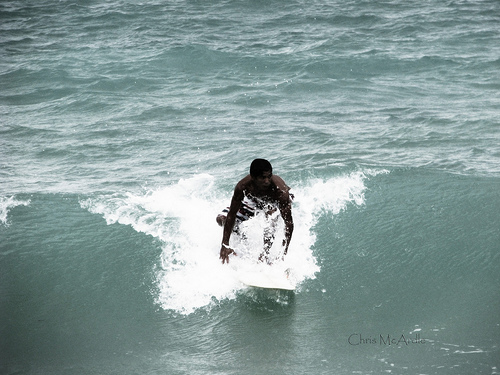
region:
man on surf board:
[179, 141, 305, 281]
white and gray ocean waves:
[350, 259, 375, 284]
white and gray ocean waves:
[282, 58, 306, 79]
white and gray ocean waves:
[42, 282, 80, 302]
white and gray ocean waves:
[193, 313, 228, 340]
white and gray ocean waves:
[286, 306, 331, 340]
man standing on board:
[207, 149, 302, 281]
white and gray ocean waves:
[367, 238, 401, 268]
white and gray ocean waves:
[347, 265, 384, 295]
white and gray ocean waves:
[46, 283, 123, 325]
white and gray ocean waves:
[93, 193, 137, 237]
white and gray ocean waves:
[385, 88, 435, 152]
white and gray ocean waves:
[280, 69, 325, 113]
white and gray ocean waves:
[182, 49, 219, 99]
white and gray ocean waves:
[136, 202, 168, 244]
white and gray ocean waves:
[129, 296, 204, 333]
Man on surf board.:
[212, 158, 303, 293]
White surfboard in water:
[237, 260, 301, 293]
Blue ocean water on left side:
[23, 228, 125, 330]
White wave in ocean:
[122, 186, 217, 306]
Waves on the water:
[48, 43, 210, 134]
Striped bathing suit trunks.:
[217, 196, 260, 231]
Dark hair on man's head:
[248, 155, 275, 193]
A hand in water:
[208, 241, 238, 268]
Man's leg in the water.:
[232, 214, 253, 246]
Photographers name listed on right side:
[341, 330, 427, 349]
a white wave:
[171, 252, 217, 299]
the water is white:
[164, 284, 206, 311]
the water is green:
[408, 173, 465, 221]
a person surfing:
[223, 163, 304, 265]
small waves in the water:
[17, 67, 114, 106]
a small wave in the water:
[314, 58, 410, 85]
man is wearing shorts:
[241, 203, 258, 221]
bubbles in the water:
[397, 315, 478, 367]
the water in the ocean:
[371, 245, 465, 320]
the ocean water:
[352, 290, 412, 330]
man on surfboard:
[197, 151, 309, 291]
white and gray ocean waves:
[340, 295, 400, 335]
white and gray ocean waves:
[33, 283, 98, 338]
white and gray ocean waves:
[399, 161, 436, 202]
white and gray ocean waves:
[39, 149, 113, 191]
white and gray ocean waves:
[382, 93, 419, 140]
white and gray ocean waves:
[146, 32, 194, 66]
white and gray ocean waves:
[333, 46, 384, 84]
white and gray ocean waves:
[249, 51, 306, 108]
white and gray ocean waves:
[179, 62, 233, 104]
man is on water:
[220, 137, 330, 253]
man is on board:
[218, 168, 310, 320]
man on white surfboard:
[217, 224, 290, 316]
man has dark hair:
[247, 143, 303, 191]